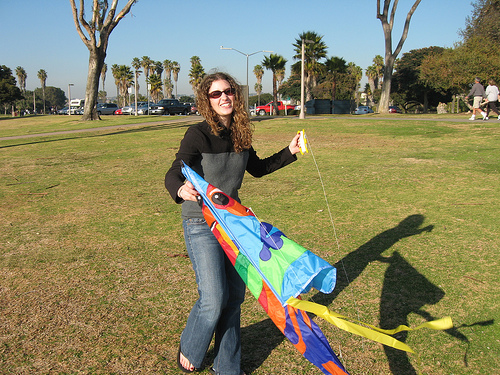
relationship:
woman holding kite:
[163, 71, 307, 373] [177, 128, 453, 374]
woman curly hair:
[163, 71, 307, 373] [194, 71, 257, 156]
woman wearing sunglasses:
[163, 71, 307, 373] [206, 87, 237, 100]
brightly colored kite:
[177, 157, 460, 374] [177, 128, 453, 374]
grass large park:
[1, 114, 498, 347] [1, 1, 498, 371]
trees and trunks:
[1, 0, 500, 130] [74, 50, 113, 125]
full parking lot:
[48, 93, 303, 126] [52, 92, 318, 131]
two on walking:
[463, 75, 500, 125] [359, 77, 500, 121]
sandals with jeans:
[171, 342, 239, 373] [177, 209, 256, 374]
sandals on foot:
[171, 342, 201, 373] [179, 351, 200, 374]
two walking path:
[463, 75, 500, 125] [269, 112, 499, 128]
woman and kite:
[163, 71, 307, 373] [177, 128, 453, 374]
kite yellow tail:
[177, 128, 453, 374] [285, 297, 458, 359]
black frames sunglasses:
[204, 128, 209, 153] [206, 87, 237, 100]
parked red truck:
[253, 98, 301, 119] [252, 99, 299, 117]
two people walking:
[463, 75, 500, 125] [359, 77, 500, 121]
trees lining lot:
[1, 0, 500, 130] [52, 92, 318, 131]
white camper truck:
[74, 101, 82, 108] [66, 97, 87, 118]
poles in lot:
[216, 44, 276, 116] [52, 92, 318, 131]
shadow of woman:
[240, 206, 486, 375] [163, 71, 307, 373]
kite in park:
[177, 128, 453, 374] [1, 1, 498, 371]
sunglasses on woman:
[206, 87, 237, 100] [163, 71, 307, 373]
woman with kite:
[163, 71, 307, 373] [177, 128, 453, 374]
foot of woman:
[179, 351, 200, 374] [163, 71, 307, 373]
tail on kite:
[285, 297, 457, 354] [177, 128, 453, 374]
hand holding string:
[286, 129, 313, 160] [295, 130, 346, 235]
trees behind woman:
[64, 0, 138, 123] [163, 71, 307, 373]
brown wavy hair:
[236, 118, 249, 145] [194, 71, 257, 156]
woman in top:
[163, 71, 307, 373] [161, 117, 301, 221]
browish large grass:
[2, 159, 154, 373] [1, 114, 498, 347]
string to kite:
[247, 130, 369, 374] [177, 128, 453, 374]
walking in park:
[359, 77, 500, 121] [1, 1, 498, 371]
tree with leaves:
[288, 56, 362, 117] [289, 62, 365, 121]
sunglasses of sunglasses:
[206, 87, 236, 99] [206, 87, 237, 100]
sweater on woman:
[160, 120, 300, 223] [163, 71, 307, 373]